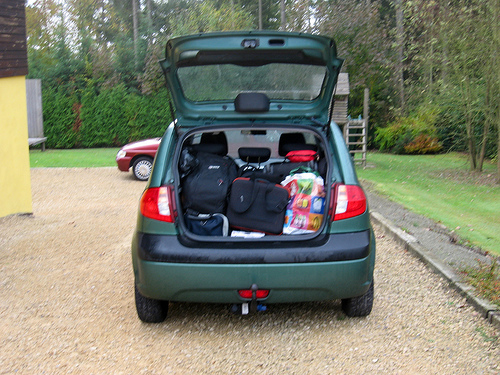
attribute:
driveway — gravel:
[26, 269, 113, 342]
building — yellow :
[1, 0, 42, 223]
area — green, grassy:
[447, 188, 496, 215]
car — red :
[113, 137, 161, 180]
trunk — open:
[164, 38, 351, 255]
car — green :
[132, 28, 375, 321]